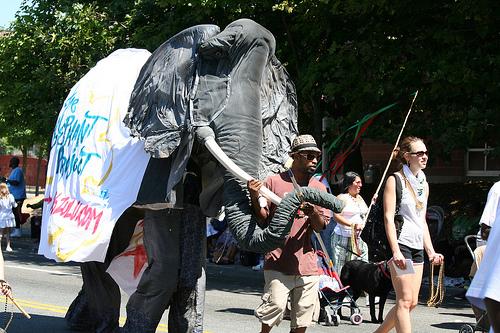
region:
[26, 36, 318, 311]
an elephant coustume with sign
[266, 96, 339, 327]
man leading elephant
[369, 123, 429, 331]
woman walking down street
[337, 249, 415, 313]
a black dog on street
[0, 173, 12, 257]
a child on street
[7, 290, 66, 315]
a double yellow line on street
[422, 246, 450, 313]
beads in womans hand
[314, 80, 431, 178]
streamer flying from pole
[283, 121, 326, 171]
man wearing hat and sunglasses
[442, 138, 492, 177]
a window in background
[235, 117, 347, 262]
The trunk of the elephant.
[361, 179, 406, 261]
The black bag the girl is carrying.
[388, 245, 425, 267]
The shorts the girl is wearing.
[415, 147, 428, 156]
The sunglasses the girl is wearing.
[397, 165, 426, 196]
The scarf around the girl's neck.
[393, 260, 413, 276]
The white paper in the girl's hand.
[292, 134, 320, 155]
The hat the guy is wearing.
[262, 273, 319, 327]
The beige shorts the guy is wearing.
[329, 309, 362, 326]
The front wheels on the stroller.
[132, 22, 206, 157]
The left ear of the elephant.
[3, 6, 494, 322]
A large mid afternoon parade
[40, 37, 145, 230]
A white banner with blue yellow and red letters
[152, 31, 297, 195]
A grey elephant costume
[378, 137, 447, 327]
A woman in black shorts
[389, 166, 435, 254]
A white tshirt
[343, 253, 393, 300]
A black dog with a red collar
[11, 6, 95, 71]
A green tree in the background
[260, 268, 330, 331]
Beige cargo shorts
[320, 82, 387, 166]
Green and red streamers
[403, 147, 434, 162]
reddish brown shades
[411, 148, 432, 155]
dark black sunglasses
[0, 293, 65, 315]
a yellow street marking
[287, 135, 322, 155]
a man's hat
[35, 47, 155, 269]
a large white sign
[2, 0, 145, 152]
part of a large green tree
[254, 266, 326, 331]
a man's brown shorts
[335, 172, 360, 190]
part of a woman's black hair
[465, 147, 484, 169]
a window of a building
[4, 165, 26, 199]
a man's short sleeve shirt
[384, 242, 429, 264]
a woman's black shorts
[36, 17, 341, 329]
two sets of human legs under an elephant costume.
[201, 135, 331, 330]
A man is holding the tusk of the elephant costume.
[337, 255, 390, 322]
A brown dog wearing a red collar.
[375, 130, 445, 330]
A woman walking on the road.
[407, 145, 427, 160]
The woman is wearing sunglasses.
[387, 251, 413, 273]
White papers in the woman's hand.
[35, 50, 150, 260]
A white cloth draped over the back of the costume.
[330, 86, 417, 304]
A woman holding a long white pole.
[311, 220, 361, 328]
A baby stroller next to the man.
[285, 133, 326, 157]
Man wearing a gray hat with a black stripe.